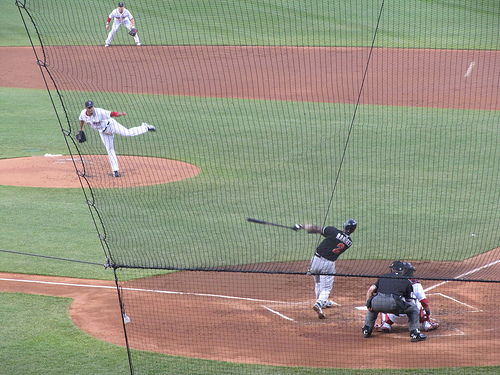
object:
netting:
[15, 2, 499, 375]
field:
[2, 1, 499, 375]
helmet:
[342, 220, 356, 232]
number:
[332, 241, 346, 256]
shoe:
[311, 303, 324, 320]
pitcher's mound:
[2, 153, 198, 189]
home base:
[352, 304, 371, 314]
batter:
[291, 218, 357, 318]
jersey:
[315, 225, 353, 264]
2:
[331, 242, 342, 252]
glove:
[76, 132, 86, 144]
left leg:
[113, 123, 157, 139]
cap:
[84, 100, 95, 110]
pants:
[308, 252, 336, 308]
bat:
[246, 217, 298, 231]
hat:
[389, 259, 405, 272]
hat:
[85, 100, 93, 109]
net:
[16, 3, 499, 374]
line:
[422, 257, 499, 293]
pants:
[366, 292, 423, 333]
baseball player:
[103, 2, 143, 47]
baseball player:
[76, 99, 154, 175]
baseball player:
[305, 216, 357, 317]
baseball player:
[380, 263, 439, 332]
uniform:
[309, 226, 355, 306]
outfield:
[2, 2, 499, 61]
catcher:
[359, 250, 424, 344]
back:
[314, 226, 358, 260]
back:
[373, 271, 413, 295]